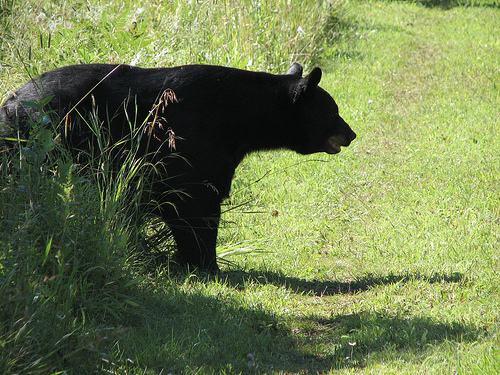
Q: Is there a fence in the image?
A: No, there are no fences.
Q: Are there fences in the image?
A: No, there are no fences.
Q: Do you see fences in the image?
A: No, there are no fences.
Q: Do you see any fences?
A: No, there are no fences.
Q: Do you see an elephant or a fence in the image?
A: No, there are no fences or elephants.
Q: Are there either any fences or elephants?
A: No, there are no fences or elephants.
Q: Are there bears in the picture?
A: Yes, there is a bear.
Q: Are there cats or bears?
A: Yes, there is a bear.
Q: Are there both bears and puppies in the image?
A: No, there is a bear but no puppies.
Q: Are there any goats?
A: No, there are no goats.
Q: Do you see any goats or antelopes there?
A: No, there are no goats or antelopes.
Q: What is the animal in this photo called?
A: The animal is a bear.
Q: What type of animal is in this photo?
A: The animal is a bear.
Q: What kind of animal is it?
A: The animal is a bear.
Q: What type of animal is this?
A: This is a bear.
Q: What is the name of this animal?
A: This is a bear.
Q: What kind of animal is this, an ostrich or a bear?
A: This is a bear.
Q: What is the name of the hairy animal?
A: The animal is a bear.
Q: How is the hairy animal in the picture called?
A: The animal is a bear.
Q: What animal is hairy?
A: The animal is a bear.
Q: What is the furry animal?
A: The animal is a bear.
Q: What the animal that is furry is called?
A: The animal is a bear.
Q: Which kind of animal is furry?
A: The animal is a bear.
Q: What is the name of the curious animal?
A: The animal is a bear.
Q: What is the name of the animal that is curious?
A: The animal is a bear.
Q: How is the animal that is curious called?
A: The animal is a bear.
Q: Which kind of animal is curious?
A: The animal is a bear.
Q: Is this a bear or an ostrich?
A: This is a bear.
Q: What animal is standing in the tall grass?
A: The bear is standing in the grass.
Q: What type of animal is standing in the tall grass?
A: The animal is a bear.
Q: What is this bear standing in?
A: The bear is standing in the grass.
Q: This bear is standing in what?
A: The bear is standing in the grass.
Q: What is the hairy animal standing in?
A: The bear is standing in the grass.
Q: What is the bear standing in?
A: The bear is standing in the grass.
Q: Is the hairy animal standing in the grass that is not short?
A: Yes, the bear is standing in the grass.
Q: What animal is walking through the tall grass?
A: The bear is walking through the grass.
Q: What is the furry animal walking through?
A: The bear is walking through the grass.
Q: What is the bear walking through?
A: The bear is walking through the grass.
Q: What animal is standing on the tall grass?
A: The bear is standing on the grass.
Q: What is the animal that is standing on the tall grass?
A: The animal is a bear.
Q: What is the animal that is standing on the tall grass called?
A: The animal is a bear.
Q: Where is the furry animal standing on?
A: The bear is standing on the grass.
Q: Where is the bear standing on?
A: The bear is standing on the grass.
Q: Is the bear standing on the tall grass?
A: Yes, the bear is standing on the grass.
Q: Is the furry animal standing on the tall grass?
A: Yes, the bear is standing on the grass.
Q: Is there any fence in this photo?
A: No, there are no fences.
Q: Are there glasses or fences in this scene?
A: No, there are no fences or glasses.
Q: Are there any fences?
A: No, there are no fences.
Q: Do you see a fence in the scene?
A: No, there are no fences.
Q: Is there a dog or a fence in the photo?
A: No, there are no fences or dogs.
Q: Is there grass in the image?
A: Yes, there is grass.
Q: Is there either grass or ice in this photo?
A: Yes, there is grass.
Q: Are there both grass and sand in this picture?
A: No, there is grass but no sand.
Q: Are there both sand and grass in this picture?
A: No, there is grass but no sand.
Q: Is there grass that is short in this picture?
A: Yes, there is short grass.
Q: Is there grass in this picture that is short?
A: Yes, there is grass that is short.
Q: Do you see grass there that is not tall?
A: Yes, there is short grass.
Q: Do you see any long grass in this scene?
A: Yes, there is long grass.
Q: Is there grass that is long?
A: Yes, there is grass that is long.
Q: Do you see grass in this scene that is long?
A: Yes, there is grass that is long.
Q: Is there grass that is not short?
A: Yes, there is long grass.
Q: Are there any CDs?
A: No, there are no cds.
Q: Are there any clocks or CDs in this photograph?
A: No, there are no CDs or clocks.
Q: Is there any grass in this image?
A: Yes, there is grass.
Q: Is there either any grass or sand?
A: Yes, there is grass.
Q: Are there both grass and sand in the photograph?
A: No, there is grass but no sand.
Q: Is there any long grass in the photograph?
A: Yes, there is long grass.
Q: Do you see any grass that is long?
A: Yes, there is grass that is long.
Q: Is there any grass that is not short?
A: Yes, there is long grass.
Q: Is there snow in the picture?
A: No, there is no snow.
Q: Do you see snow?
A: No, there is no snow.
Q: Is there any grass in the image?
A: Yes, there is grass.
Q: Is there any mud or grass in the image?
A: Yes, there is grass.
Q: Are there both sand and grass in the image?
A: No, there is grass but no sand.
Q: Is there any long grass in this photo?
A: Yes, there is long grass.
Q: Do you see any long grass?
A: Yes, there is long grass.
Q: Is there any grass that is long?
A: Yes, there is grass that is long.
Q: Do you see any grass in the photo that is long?
A: Yes, there is grass that is long.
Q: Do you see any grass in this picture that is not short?
A: Yes, there is long grass.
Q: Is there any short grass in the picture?
A: Yes, there is short grass.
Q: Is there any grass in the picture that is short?
A: Yes, there is grass that is short.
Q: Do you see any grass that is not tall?
A: Yes, there is short grass.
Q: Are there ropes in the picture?
A: No, there are no ropes.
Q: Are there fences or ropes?
A: No, there are no ropes or fences.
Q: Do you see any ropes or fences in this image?
A: No, there are no ropes or fences.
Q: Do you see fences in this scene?
A: No, there are no fences.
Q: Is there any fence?
A: No, there are no fences.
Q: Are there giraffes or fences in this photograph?
A: No, there are no fences or giraffes.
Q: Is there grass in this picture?
A: Yes, there is grass.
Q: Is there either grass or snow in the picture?
A: Yes, there is grass.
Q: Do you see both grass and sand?
A: No, there is grass but no sand.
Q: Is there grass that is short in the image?
A: Yes, there is short grass.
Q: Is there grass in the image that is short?
A: Yes, there is grass that is short.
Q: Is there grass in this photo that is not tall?
A: Yes, there is short grass.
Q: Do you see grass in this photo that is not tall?
A: Yes, there is short grass.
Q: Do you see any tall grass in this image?
A: Yes, there is tall grass.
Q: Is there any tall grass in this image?
A: Yes, there is tall grass.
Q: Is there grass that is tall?
A: Yes, there is grass that is tall.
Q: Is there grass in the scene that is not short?
A: Yes, there is tall grass.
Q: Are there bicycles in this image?
A: No, there are no bicycles.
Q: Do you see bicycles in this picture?
A: No, there are no bicycles.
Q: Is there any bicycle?
A: No, there are no bicycles.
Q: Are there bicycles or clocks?
A: No, there are no bicycles or clocks.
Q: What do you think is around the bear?
A: The grass is around the bear.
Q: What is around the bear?
A: The grass is around the bear.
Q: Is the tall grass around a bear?
A: Yes, the grass is around a bear.